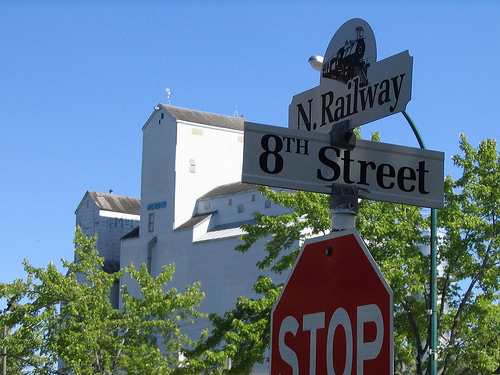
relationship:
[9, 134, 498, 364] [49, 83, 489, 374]
tree in front of building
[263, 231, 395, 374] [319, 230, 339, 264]
sign has metal